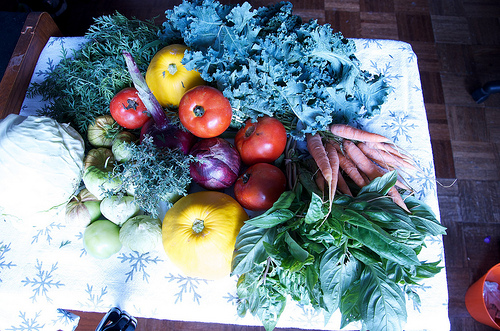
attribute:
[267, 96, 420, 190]
carrots — bunched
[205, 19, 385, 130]
kale — loose